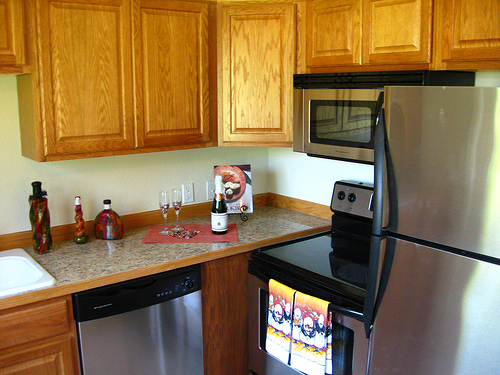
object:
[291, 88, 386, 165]
microwave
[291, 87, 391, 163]
steel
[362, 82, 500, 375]
fridge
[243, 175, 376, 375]
stove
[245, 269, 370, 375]
steel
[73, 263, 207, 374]
dishwasher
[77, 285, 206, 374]
steel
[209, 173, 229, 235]
wine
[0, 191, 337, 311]
counter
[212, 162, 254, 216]
book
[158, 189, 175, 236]
glasses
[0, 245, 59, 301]
sink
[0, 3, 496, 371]
kitchen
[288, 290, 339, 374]
towels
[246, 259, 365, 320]
handle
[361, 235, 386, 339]
handles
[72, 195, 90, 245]
bottles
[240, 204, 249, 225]
stand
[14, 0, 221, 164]
cabinets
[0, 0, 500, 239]
wall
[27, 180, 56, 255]
bottle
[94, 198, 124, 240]
jar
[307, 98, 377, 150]
window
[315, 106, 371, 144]
light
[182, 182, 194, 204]
socket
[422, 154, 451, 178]
smudges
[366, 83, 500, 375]
door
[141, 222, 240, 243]
placemat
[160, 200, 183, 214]
candy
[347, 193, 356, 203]
knobs